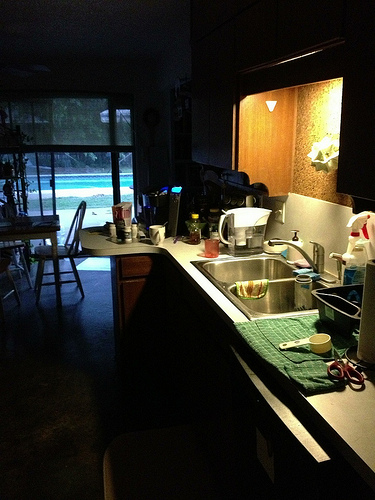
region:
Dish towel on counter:
[236, 313, 361, 392]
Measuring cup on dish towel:
[278, 332, 331, 351]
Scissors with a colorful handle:
[326, 347, 364, 389]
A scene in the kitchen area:
[79, 14, 373, 498]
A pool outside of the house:
[0, 150, 136, 193]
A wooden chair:
[34, 195, 88, 300]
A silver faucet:
[266, 239, 332, 285]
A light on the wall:
[297, 83, 346, 173]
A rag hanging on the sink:
[229, 278, 271, 301]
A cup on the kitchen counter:
[147, 220, 168, 243]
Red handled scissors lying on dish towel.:
[329, 347, 368, 390]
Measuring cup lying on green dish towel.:
[277, 326, 339, 360]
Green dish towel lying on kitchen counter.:
[242, 319, 334, 394]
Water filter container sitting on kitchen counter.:
[214, 203, 273, 258]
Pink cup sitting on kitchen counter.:
[203, 238, 222, 260]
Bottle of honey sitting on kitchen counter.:
[185, 211, 202, 248]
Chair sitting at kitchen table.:
[32, 200, 87, 304]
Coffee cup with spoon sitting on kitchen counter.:
[145, 215, 176, 245]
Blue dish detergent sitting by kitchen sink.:
[342, 235, 368, 285]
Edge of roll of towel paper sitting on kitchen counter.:
[353, 253, 373, 373]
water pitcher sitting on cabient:
[216, 201, 274, 263]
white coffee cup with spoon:
[146, 215, 169, 252]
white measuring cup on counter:
[275, 331, 334, 358]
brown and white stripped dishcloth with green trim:
[227, 265, 277, 307]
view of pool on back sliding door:
[25, 160, 135, 221]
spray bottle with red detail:
[333, 201, 371, 292]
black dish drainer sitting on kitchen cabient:
[305, 275, 373, 355]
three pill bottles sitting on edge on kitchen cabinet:
[100, 215, 153, 255]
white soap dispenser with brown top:
[283, 223, 307, 270]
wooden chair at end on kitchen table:
[1, 184, 107, 313]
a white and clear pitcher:
[214, 206, 270, 253]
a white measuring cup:
[277, 330, 329, 351]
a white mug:
[146, 222, 162, 243]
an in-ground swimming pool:
[0, 169, 132, 187]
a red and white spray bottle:
[338, 210, 368, 281]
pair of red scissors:
[325, 346, 361, 378]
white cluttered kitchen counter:
[76, 225, 369, 488]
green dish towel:
[229, 311, 351, 393]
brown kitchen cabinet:
[187, 0, 372, 210]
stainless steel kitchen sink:
[188, 238, 347, 326]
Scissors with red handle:
[328, 350, 364, 390]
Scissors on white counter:
[325, 347, 367, 394]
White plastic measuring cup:
[275, 330, 334, 356]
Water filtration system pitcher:
[216, 208, 278, 256]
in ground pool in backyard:
[0, 162, 136, 209]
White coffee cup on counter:
[145, 221, 167, 246]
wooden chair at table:
[27, 204, 85, 311]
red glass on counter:
[199, 237, 225, 258]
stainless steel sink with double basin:
[190, 236, 327, 308]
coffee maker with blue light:
[139, 183, 185, 240]